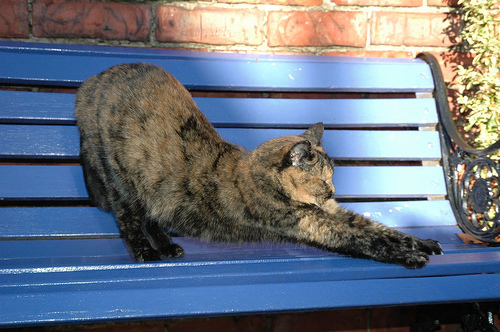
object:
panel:
[0, 41, 434, 93]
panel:
[0, 91, 437, 126]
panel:
[1, 124, 441, 161]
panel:
[0, 165, 447, 200]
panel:
[0, 200, 457, 239]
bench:
[0, 40, 499, 325]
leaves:
[472, 53, 484, 64]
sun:
[249, 54, 457, 226]